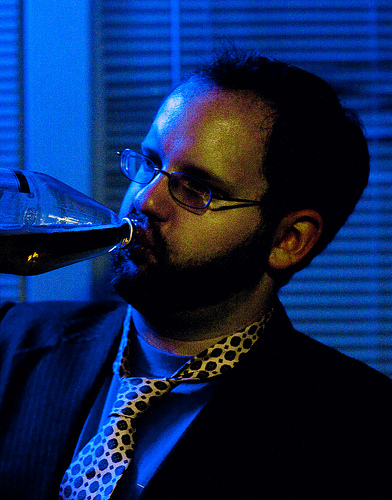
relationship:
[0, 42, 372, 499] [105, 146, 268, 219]
man wearing glasses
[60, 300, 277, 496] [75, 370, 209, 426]
knot has knot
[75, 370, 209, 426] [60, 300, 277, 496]
knot on knot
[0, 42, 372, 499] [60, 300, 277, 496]
man wearing knot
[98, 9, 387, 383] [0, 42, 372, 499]
blind behind man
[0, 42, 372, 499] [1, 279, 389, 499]
man wearing jacket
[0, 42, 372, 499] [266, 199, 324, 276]
man has ear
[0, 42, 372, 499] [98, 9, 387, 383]
man in front of blind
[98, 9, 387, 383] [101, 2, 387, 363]
blind in front of window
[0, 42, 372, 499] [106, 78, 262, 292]
man has face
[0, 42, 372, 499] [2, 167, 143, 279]
man holding bottle